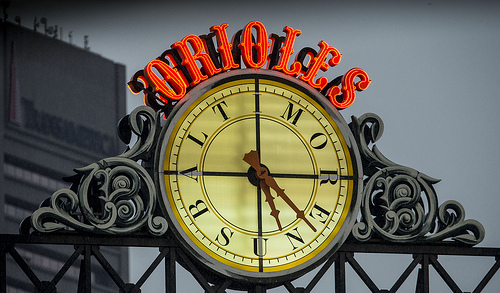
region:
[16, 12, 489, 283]
the 'baltimore sun' @ oriole park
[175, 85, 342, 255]
the letters 'b a l t i m o r e s u n' stand in for the clock's numbers [even tho there's one too many, which must get confusing]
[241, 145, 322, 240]
clock's hands are rust red+a touch ornate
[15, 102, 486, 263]
almost baroque placement on sides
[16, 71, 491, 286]
shiny black metal, maybe lacquered, setting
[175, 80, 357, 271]
clock divided in fourths, although how that helps w/ the 13 number problem i know not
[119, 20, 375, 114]
a bright red - yellow - orange 'orioles' up top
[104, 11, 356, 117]
same 'orioles' same colour on back, just going the opposite direction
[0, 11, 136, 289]
a tall grey building, multiply windowed, to left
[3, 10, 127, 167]
'transamerica' building+its logo, also a bunch of curious items on its roof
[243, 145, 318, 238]
metal hands of a clock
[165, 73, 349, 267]
round yellow clock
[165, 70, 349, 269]
round clock with no numbers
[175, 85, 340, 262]
black letters in a round clock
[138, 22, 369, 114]
bright orange letters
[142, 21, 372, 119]
orange letters above round clock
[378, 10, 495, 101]
dark grey sky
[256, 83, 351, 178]
black tick marks in clock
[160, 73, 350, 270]
gold ring inside clock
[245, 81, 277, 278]
black vertical line in clock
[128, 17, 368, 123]
Neon orange Orioles sign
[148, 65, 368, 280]
Clock under Orioles sign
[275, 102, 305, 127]
Letter "M" on clock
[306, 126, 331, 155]
Letter "O" on clock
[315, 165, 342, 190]
Letter "R" on clock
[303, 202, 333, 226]
Letter "E" on clock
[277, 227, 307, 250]
Letter "N" on clock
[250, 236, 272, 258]
Letter "U" on clock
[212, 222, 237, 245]
Letter "S" on clock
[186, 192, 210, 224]
Letter "B" on clock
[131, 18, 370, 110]
A neon orioles sign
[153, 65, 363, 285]
A clock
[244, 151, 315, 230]
The minute hand of the clock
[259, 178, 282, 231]
The hour hand of the clock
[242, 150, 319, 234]
The hands of the clock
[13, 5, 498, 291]
A grey cloudy sky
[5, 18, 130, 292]
A large grey building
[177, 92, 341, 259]
Some letters on the clock face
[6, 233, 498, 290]
A metal support post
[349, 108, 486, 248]
some metal flourish next to the clock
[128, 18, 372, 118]
orange orioles sign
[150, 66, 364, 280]
yellowish baltimore sun clock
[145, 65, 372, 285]
clock face that reads 5:22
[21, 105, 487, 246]
intricate circle designs by the clock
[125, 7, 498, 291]
gray overcast skies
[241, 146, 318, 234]
brown hands of the clock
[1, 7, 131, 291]
gray building in the background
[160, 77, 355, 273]
gold border around the clock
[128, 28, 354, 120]
duplicate orioles sign behind the front face of the orioles sign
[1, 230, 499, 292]
black support posts for the clock